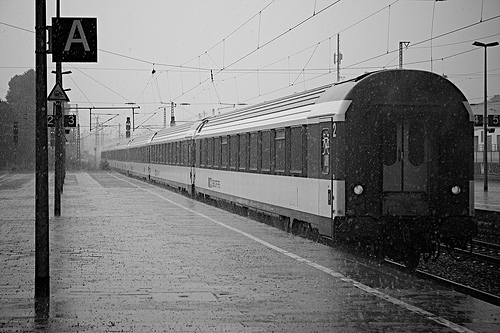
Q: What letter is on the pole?
A: A.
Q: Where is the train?
A: On the tracks.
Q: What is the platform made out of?
A: Brick.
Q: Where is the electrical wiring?
A: Above the train.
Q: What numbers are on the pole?
A: 2 and 3.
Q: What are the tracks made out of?
A: Metal.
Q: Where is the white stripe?
A: Along the edge of the platform.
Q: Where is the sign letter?
A: On the pole.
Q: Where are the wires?
A: Along the top of the train.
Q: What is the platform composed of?
A: Bricks.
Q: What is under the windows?
A: A light stripe.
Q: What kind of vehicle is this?
A: Train.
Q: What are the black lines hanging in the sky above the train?
A: Power lines.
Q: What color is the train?
A: Silver and black.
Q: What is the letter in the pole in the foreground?
A: A.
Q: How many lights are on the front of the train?
A: Two.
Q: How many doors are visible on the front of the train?
A: Two.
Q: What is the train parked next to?
A: Platform.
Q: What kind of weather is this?
A: Rain.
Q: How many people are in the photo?
A: None.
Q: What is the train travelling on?
A: Train tracks.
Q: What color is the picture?
A: Black and white.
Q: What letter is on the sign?
A: A.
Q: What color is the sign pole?
A: Black.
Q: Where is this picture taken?
A: A train station.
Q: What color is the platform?
A: Grey.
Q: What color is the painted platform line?
A: White.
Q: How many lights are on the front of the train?
A: Two.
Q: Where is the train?
A: At the station.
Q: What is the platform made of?
A: Bricks.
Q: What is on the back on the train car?
A: Doors.